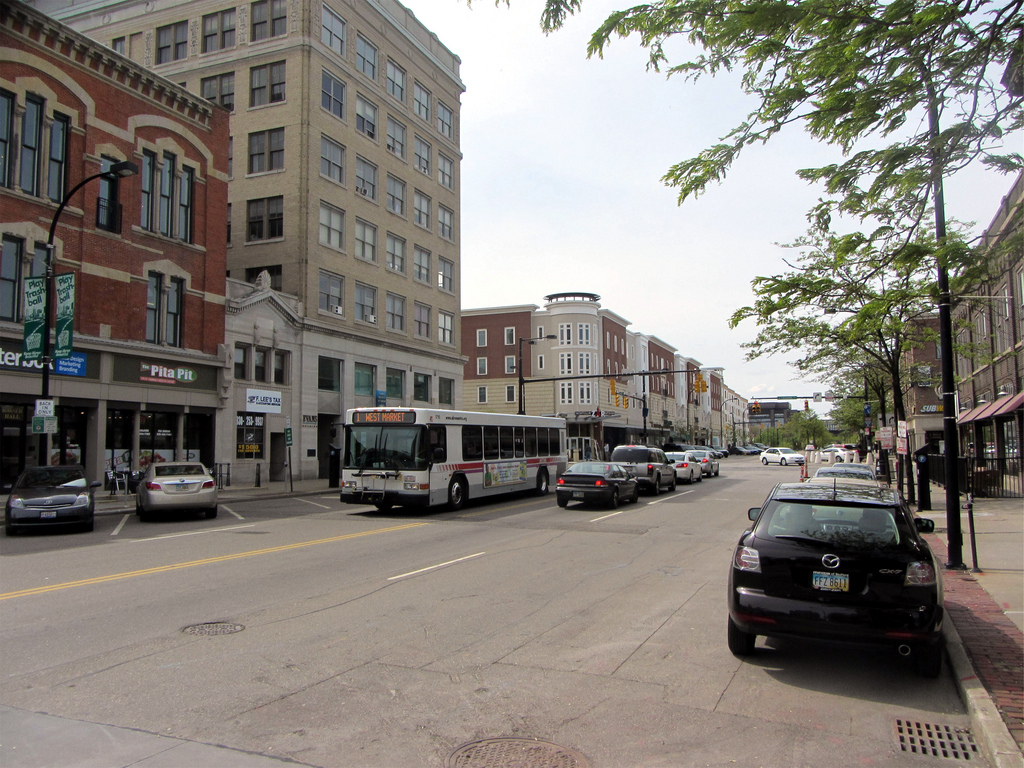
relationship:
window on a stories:
[147, 158, 195, 237] [0, 0, 230, 501]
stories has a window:
[0, 0, 230, 501] [147, 158, 195, 237]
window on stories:
[147, 158, 195, 237] [0, 0, 230, 501]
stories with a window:
[0, 0, 230, 501] [147, 158, 195, 237]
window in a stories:
[147, 158, 195, 237] [0, 0, 230, 501]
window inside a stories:
[147, 158, 195, 237] [0, 0, 230, 501]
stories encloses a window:
[0, 0, 230, 501] [147, 158, 195, 237]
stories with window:
[0, 0, 230, 501] [147, 158, 195, 237]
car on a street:
[728, 481, 948, 694] [310, 525, 464, 611]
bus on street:
[346, 407, 558, 508] [310, 525, 464, 611]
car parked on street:
[728, 481, 948, 694] [310, 525, 464, 611]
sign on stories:
[134, 358, 195, 391] [0, 0, 230, 501]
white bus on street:
[447, 430, 463, 460] [310, 525, 464, 611]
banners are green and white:
[22, 281, 71, 360] [447, 430, 463, 460]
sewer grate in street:
[886, 708, 986, 767] [310, 525, 464, 611]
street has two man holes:
[310, 525, 464, 611] [185, 610, 245, 649]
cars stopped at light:
[553, 447, 724, 517] [686, 373, 718, 404]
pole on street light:
[50, 177, 96, 217] [686, 373, 718, 404]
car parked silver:
[138, 451, 222, 523] [172, 496, 197, 501]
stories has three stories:
[0, 0, 230, 501] [140, 141, 220, 463]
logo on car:
[817, 548, 847, 573] [728, 481, 948, 694]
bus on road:
[346, 407, 558, 508] [476, 556, 568, 606]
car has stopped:
[728, 481, 948, 694] [553, 472, 614, 496]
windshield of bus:
[353, 429, 423, 468] [346, 407, 558, 508]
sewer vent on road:
[886, 708, 986, 767] [476, 556, 568, 606]